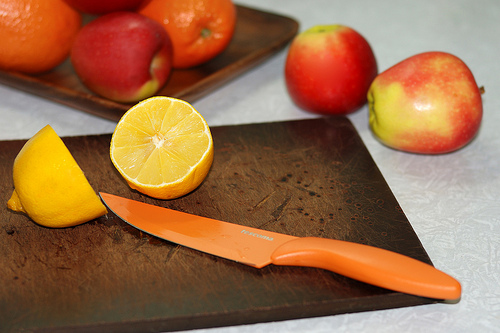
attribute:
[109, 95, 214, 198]
lemon — sliced, cut, halved, yellow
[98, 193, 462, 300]
knife — orange, plastic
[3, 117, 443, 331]
cutting board — brown, wood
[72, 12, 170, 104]
apple — yellow, red, whole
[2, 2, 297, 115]
cutting board — wooden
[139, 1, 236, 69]
orange — rippled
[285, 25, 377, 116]
apple — red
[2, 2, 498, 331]
table — gray, white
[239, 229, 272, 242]
writting — white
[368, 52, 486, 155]
apple — red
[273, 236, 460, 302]
handle — orange